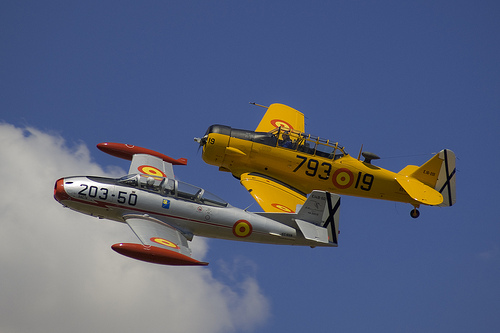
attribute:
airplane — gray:
[53, 141, 343, 267]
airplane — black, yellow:
[192, 101, 457, 219]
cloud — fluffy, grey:
[0, 121, 271, 332]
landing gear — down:
[409, 205, 420, 219]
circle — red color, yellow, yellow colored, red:
[231, 220, 254, 239]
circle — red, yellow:
[330, 167, 353, 189]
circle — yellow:
[138, 165, 167, 181]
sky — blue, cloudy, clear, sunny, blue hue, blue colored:
[0, 0, 499, 333]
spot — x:
[322, 190, 342, 243]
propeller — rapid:
[193, 128, 209, 155]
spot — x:
[438, 147, 455, 208]